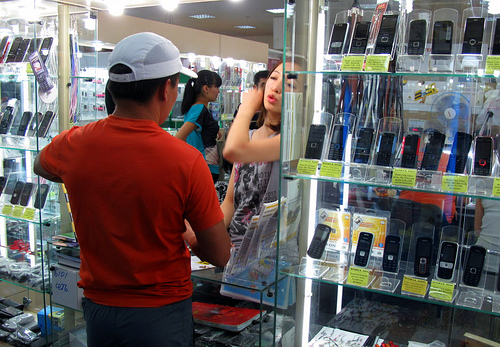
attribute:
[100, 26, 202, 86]
cap — white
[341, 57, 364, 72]
label — green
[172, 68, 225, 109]
hair — ponytail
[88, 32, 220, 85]
cap — white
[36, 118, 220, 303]
shirt — blue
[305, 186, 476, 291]
phone — black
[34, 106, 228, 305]
shirt — blue, orange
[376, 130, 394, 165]
phone — black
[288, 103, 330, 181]
phone — black, red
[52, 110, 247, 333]
shirt — red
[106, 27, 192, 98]
hat — white